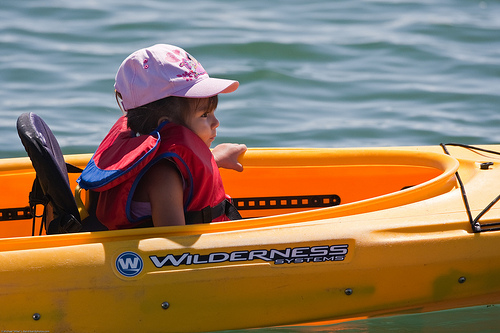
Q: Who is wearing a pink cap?
A: Child in a canoe.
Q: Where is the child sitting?
A: In a canoe.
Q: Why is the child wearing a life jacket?
A: In a kayak.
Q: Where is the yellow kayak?
A: In the water.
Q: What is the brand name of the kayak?
A: Wilderness Systems.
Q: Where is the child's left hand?
A: On the gunwale.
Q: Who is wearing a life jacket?
A: Little girl.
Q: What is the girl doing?
A: Riding in a boat.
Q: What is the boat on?
A: The water.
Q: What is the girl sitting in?
A: A seat in the boat.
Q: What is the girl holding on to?
A: The ide of the boat.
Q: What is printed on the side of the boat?
A: A decal.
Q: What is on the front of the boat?
A: Bungee cords.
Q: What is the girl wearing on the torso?
A: A life vest.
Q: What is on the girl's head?
A: A hat.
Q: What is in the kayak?
A: A girl.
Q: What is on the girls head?
A: A hat.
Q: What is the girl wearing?
A: A life jacket.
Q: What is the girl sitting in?
A: A kayak.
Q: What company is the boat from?
A: Wilderness Systems.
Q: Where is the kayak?
A: On the water.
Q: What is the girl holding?
A: The kayak.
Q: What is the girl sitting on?
A: A seat.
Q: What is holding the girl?
A: A seatbelt.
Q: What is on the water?
A: A kayak.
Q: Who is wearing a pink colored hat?
A: Child.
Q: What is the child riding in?
A: Boat.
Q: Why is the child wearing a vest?
A: Safety.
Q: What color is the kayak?
A: Yellow.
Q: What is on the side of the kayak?
A: Wilderness Systems.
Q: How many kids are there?
A: One.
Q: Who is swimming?
A: No one.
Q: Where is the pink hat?
A: On kids head.